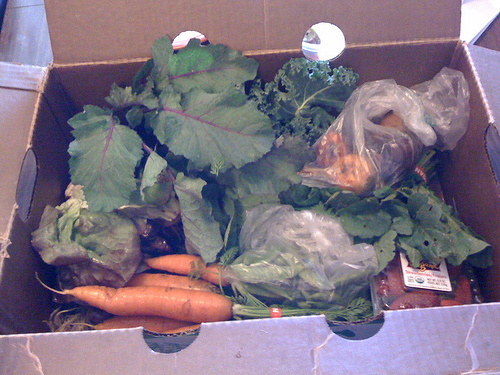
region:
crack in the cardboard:
[459, 306, 489, 371]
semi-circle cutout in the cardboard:
[134, 323, 205, 357]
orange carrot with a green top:
[31, 273, 333, 335]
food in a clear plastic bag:
[300, 94, 461, 199]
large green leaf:
[109, 75, 281, 175]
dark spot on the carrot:
[178, 298, 194, 316]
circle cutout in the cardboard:
[293, 13, 365, 70]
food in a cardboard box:
[1, 3, 497, 373]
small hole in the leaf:
[418, 233, 433, 250]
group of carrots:
[61, 253, 246, 341]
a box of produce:
[43, 50, 494, 325]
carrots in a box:
[47, 243, 338, 333]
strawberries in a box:
[375, 242, 480, 303]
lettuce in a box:
[83, 55, 247, 195]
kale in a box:
[251, 47, 353, 121]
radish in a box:
[310, 84, 450, 202]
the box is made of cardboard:
[18, 37, 498, 325]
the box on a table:
[3, 37, 498, 338]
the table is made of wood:
[11, 5, 44, 46]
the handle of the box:
[0, 117, 41, 218]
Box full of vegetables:
[36, 45, 489, 304]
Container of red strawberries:
[359, 221, 498, 368]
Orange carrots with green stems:
[39, 252, 346, 332]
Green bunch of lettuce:
[82, 67, 305, 197]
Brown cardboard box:
[7, 60, 71, 202]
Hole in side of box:
[291, 5, 378, 90]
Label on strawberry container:
[377, 247, 468, 334]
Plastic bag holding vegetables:
[251, 197, 384, 303]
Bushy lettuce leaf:
[256, 47, 423, 147]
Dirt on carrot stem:
[105, 276, 232, 330]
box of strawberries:
[348, 217, 497, 329]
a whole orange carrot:
[49, 243, 258, 328]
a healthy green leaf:
[70, 29, 260, 218]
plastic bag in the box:
[228, 161, 372, 289]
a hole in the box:
[277, 11, 364, 68]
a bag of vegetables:
[305, 49, 477, 222]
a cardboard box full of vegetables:
[27, 14, 470, 374]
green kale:
[240, 50, 402, 160]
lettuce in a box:
[363, 180, 473, 267]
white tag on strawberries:
[388, 231, 459, 296]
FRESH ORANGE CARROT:
[45, 281, 235, 319]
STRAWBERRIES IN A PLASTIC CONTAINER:
[375, 280, 447, 302]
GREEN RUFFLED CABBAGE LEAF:
[266, 65, 326, 135]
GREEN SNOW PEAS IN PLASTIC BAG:
[236, 236, 371, 306]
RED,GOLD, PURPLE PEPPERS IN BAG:
[320, 130, 396, 188]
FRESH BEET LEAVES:
[82, 85, 242, 211]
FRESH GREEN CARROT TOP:
[222, 295, 359, 321]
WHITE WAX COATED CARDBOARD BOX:
[85, 328, 460, 371]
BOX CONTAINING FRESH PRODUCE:
[28, 56, 478, 364]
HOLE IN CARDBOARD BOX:
[289, 20, 361, 67]